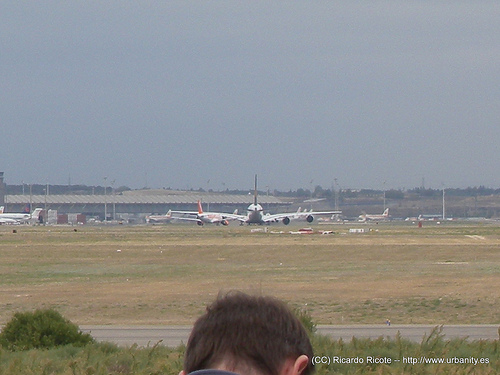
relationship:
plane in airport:
[168, 172, 340, 228] [0, 185, 496, 223]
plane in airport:
[356, 205, 388, 221] [0, 185, 496, 223]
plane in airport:
[143, 207, 173, 225] [0, 185, 496, 223]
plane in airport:
[0, 205, 44, 225] [0, 185, 496, 223]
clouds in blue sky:
[0, 0, 499, 189] [0, 0, 500, 191]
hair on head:
[182, 287, 322, 363] [177, 264, 320, 372]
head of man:
[177, 264, 320, 372] [153, 282, 331, 373]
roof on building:
[4, 187, 294, 209] [1, 185, 296, 226]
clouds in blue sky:
[0, 0, 499, 189] [396, 20, 472, 77]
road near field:
[74, 322, 496, 350] [0, 224, 497, 324]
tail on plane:
[195, 200, 206, 217] [181, 199, 240, 224]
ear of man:
[289, 357, 309, 373] [176, 289, 317, 374]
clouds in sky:
[0, 0, 499, 189] [226, 49, 362, 129]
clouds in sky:
[0, 0, 499, 189] [24, 22, 489, 162]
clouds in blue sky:
[234, 52, 311, 157] [0, 0, 500, 191]